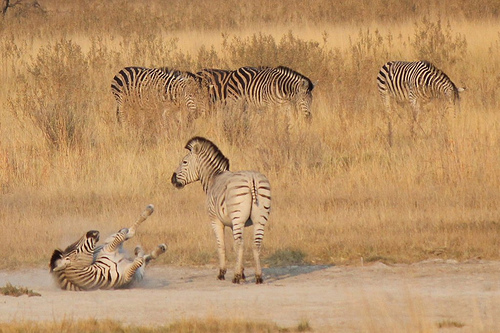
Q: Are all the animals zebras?
A: Yes, all the animals are zebras.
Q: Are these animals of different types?
A: No, all the animals are zebras.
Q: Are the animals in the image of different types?
A: No, all the animals are zebras.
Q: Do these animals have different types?
A: No, all the animals are zebras.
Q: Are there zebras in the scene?
A: Yes, there is a zebra.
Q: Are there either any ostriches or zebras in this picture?
A: Yes, there is a zebra.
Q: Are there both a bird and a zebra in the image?
A: No, there is a zebra but no birds.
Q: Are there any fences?
A: No, there are no fences.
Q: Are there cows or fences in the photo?
A: No, there are no fences or cows.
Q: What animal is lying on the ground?
A: The zebra is lying on the ground.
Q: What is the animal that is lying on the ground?
A: The animal is a zebra.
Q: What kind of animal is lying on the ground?
A: The animal is a zebra.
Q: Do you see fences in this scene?
A: No, there are no fences.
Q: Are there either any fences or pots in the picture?
A: No, there are no fences or pots.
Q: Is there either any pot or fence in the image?
A: No, there are no fences or pots.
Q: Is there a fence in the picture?
A: No, there are no fences.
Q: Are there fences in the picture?
A: No, there are no fences.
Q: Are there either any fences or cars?
A: No, there are no fences or cars.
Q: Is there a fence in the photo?
A: No, there are no fences.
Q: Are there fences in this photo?
A: No, there are no fences.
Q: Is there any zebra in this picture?
A: Yes, there is a zebra.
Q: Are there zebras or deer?
A: Yes, there is a zebra.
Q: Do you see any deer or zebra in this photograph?
A: Yes, there is a zebra.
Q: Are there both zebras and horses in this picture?
A: No, there is a zebra but no horses.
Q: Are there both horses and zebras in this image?
A: No, there is a zebra but no horses.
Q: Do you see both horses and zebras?
A: No, there is a zebra but no horses.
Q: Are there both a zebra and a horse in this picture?
A: No, there is a zebra but no horses.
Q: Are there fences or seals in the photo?
A: No, there are no fences or seals.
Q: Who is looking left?
A: The zebra is looking left.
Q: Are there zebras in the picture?
A: Yes, there are zebras.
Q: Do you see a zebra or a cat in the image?
A: Yes, there are zebras.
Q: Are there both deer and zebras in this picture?
A: No, there are zebras but no deer.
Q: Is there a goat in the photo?
A: No, there are no goats.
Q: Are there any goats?
A: No, there are no goats.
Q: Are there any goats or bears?
A: No, there are no goats or bears.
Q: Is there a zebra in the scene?
A: Yes, there is a zebra.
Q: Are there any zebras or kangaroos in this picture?
A: Yes, there is a zebra.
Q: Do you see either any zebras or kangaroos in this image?
A: Yes, there is a zebra.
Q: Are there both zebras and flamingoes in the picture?
A: No, there is a zebra but no flamingoes.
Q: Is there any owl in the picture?
A: No, there are no owls.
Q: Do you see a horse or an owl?
A: No, there are no owls or horses.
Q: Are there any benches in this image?
A: No, there are no benches.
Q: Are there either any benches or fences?
A: No, there are no benches or fences.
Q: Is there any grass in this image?
A: Yes, there is grass.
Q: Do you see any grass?
A: Yes, there is grass.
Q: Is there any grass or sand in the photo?
A: Yes, there is grass.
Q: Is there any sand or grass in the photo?
A: Yes, there is grass.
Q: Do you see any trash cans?
A: No, there are no trash cans.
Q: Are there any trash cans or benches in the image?
A: No, there are no trash cans or benches.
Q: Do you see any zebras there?
A: Yes, there is a zebra.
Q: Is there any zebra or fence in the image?
A: Yes, there is a zebra.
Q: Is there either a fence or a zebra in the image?
A: Yes, there is a zebra.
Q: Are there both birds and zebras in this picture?
A: No, there is a zebra but no birds.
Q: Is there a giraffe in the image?
A: No, there are no giraffes.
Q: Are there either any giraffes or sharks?
A: No, there are no giraffes or sharks.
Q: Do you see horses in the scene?
A: No, there are no horses.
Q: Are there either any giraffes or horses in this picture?
A: No, there are no horses or giraffes.